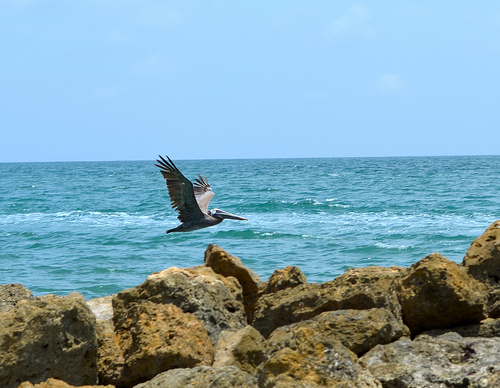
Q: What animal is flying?
A: A bird.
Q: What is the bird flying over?
A: Rocks.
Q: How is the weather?
A: Sunny and clear.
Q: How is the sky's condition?
A: Blue and clear.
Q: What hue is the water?
A: Bright blue.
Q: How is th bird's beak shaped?
A: Very pointy.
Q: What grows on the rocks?
A: Moss.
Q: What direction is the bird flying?
A: Right.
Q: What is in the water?
A: A wave.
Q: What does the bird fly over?
A: The crystal blue ocean.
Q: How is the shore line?
A: Rocky shore line.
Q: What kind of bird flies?
A: A pelican.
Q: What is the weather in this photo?
A: Sunny and clear.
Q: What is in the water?
A: Waves cresting.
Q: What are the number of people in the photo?
A: There are zero people.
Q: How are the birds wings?
A: The wings are expanded in flight.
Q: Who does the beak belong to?
A: Belongs to the pelican.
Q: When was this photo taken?
A: Day time.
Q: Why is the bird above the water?
A: It is flying.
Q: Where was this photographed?
A: The ocean.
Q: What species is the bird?
A: Albatross.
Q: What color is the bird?
A: Gray.